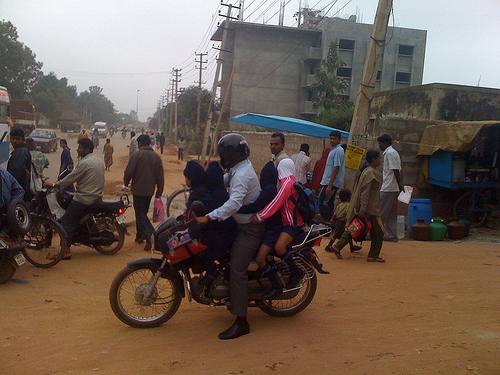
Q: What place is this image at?
A: It is at the town.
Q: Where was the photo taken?
A: It was taken at the town.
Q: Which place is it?
A: It is a town.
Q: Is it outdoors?
A: Yes, it is outdoors.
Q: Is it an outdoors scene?
A: Yes, it is outdoors.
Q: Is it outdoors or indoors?
A: It is outdoors.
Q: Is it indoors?
A: No, it is outdoors.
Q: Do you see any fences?
A: No, there are no fences.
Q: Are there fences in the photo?
A: No, there are no fences.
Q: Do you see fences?
A: No, there are no fences.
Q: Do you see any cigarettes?
A: No, there are no cigarettes.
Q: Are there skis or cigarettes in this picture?
A: No, there are no cigarettes or skis.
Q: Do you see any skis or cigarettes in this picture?
A: No, there are no cigarettes or skis.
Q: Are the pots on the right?
A: Yes, the pots are on the right of the image.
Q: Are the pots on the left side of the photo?
A: No, the pots are on the right of the image.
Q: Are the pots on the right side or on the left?
A: The pots are on the right of the image.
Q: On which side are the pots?
A: The pots are on the right of the image.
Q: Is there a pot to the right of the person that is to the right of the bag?
A: Yes, there are pots to the right of the person.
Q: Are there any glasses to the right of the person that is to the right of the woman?
A: No, there are pots to the right of the person.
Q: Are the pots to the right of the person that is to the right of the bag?
A: Yes, the pots are to the right of the person.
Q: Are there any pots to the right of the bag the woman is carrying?
A: Yes, there are pots to the right of the bag.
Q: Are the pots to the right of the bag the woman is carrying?
A: Yes, the pots are to the right of the bag.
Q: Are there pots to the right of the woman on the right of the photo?
A: Yes, there are pots to the right of the woman.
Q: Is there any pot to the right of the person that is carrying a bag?
A: Yes, there are pots to the right of the woman.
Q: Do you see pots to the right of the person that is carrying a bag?
A: Yes, there are pots to the right of the woman.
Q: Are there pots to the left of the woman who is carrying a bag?
A: No, the pots are to the right of the woman.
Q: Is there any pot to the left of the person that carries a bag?
A: No, the pots are to the right of the woman.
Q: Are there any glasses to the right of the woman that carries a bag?
A: No, there are pots to the right of the woman.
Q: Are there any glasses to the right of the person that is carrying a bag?
A: No, there are pots to the right of the woman.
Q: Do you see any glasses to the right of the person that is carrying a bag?
A: No, there are pots to the right of the woman.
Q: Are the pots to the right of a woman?
A: Yes, the pots are to the right of a woman.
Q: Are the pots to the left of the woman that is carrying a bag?
A: No, the pots are to the right of the woman.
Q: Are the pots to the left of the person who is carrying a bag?
A: No, the pots are to the right of the woman.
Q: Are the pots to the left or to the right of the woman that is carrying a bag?
A: The pots are to the right of the woman.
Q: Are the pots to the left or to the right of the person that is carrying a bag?
A: The pots are to the right of the woman.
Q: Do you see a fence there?
A: No, there are no fences.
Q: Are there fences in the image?
A: No, there are no fences.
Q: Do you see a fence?
A: No, there are no fences.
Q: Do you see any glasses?
A: No, there are no glasses.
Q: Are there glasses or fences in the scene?
A: No, there are no glasses or fences.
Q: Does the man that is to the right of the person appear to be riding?
A: Yes, the man is riding.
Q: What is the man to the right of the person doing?
A: The man is riding.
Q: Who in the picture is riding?
A: The man is riding.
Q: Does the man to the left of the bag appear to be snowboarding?
A: No, the man is riding.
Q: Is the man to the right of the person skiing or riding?
A: The man is riding.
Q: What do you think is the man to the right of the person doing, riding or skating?
A: The man is riding.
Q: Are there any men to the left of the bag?
A: Yes, there is a man to the left of the bag.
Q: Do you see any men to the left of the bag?
A: Yes, there is a man to the left of the bag.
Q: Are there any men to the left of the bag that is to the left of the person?
A: Yes, there is a man to the left of the bag.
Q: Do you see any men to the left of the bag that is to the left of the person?
A: Yes, there is a man to the left of the bag.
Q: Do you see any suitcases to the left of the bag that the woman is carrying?
A: No, there is a man to the left of the bag.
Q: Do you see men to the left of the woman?
A: Yes, there is a man to the left of the woman.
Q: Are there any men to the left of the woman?
A: Yes, there is a man to the left of the woman.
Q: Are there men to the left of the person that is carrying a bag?
A: Yes, there is a man to the left of the woman.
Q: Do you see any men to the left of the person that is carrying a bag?
A: Yes, there is a man to the left of the woman.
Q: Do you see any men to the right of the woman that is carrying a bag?
A: No, the man is to the left of the woman.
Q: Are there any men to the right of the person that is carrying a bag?
A: No, the man is to the left of the woman.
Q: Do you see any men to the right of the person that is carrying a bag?
A: No, the man is to the left of the woman.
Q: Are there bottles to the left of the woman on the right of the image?
A: No, there is a man to the left of the woman.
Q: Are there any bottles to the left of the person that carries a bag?
A: No, there is a man to the left of the woman.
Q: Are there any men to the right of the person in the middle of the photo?
A: Yes, there is a man to the right of the person.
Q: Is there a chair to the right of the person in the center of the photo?
A: No, there is a man to the right of the person.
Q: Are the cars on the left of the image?
A: Yes, the cars are on the left of the image.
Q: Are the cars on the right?
A: No, the cars are on the left of the image.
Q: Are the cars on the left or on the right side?
A: The cars are on the left of the image.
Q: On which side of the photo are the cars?
A: The cars are on the left of the image.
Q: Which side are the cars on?
A: The cars are on the left of the image.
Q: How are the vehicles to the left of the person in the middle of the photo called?
A: The vehicles are cars.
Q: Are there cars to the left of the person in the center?
A: Yes, there are cars to the left of the person.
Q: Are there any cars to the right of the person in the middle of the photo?
A: No, the cars are to the left of the person.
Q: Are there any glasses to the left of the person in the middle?
A: No, there are cars to the left of the person.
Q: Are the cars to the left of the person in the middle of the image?
A: Yes, the cars are to the left of the person.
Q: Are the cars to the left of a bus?
A: No, the cars are to the left of the person.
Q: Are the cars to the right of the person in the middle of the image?
A: No, the cars are to the left of the person.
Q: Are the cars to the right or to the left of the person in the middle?
A: The cars are to the left of the person.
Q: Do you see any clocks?
A: No, there are no clocks.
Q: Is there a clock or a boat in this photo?
A: No, there are no clocks or boats.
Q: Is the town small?
A: Yes, the town is small.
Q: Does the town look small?
A: Yes, the town is small.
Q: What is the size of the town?
A: The town is small.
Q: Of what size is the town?
A: The town is small.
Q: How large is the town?
A: The town is small.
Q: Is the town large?
A: No, the town is small.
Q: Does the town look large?
A: No, the town is small.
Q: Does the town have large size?
A: No, the town is small.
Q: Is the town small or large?
A: The town is small.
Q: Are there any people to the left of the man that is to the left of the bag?
A: Yes, there is a person to the left of the man.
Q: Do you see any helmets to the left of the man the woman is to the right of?
A: No, there is a person to the left of the man.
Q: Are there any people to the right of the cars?
A: Yes, there is a person to the right of the cars.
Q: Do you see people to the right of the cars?
A: Yes, there is a person to the right of the cars.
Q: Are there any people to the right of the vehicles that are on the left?
A: Yes, there is a person to the right of the cars.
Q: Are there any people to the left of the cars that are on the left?
A: No, the person is to the right of the cars.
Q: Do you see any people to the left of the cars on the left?
A: No, the person is to the right of the cars.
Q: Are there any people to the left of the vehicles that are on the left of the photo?
A: No, the person is to the right of the cars.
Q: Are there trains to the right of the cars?
A: No, there is a person to the right of the cars.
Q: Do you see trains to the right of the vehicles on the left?
A: No, there is a person to the right of the cars.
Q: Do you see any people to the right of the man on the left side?
A: Yes, there is a person to the right of the man.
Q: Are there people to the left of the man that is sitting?
A: No, the person is to the right of the man.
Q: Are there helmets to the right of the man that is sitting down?
A: No, there is a person to the right of the man.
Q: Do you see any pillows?
A: No, there are no pillows.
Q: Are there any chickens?
A: No, there are no chickens.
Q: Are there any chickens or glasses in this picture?
A: No, there are no chickens or glasses.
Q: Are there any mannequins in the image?
A: No, there are no mannequins.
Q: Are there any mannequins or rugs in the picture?
A: No, there are no mannequins or rugs.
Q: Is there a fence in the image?
A: No, there are no fences.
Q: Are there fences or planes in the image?
A: No, there are no fences or planes.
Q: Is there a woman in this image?
A: Yes, there is a woman.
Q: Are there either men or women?
A: Yes, there is a woman.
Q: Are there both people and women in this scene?
A: Yes, there are both a woman and people.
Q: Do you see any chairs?
A: No, there are no chairs.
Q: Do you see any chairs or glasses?
A: No, there are no chairs or glasses.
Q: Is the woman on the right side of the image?
A: Yes, the woman is on the right of the image.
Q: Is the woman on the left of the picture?
A: No, the woman is on the right of the image.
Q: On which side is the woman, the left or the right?
A: The woman is on the right of the image.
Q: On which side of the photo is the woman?
A: The woman is on the right of the image.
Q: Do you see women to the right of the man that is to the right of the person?
A: Yes, there is a woman to the right of the man.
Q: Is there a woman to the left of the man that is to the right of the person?
A: No, the woman is to the right of the man.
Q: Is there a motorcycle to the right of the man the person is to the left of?
A: No, there is a woman to the right of the man.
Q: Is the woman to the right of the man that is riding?
A: Yes, the woman is to the right of the man.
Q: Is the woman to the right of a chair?
A: No, the woman is to the right of the man.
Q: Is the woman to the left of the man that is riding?
A: No, the woman is to the right of the man.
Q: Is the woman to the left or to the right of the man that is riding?
A: The woman is to the right of the man.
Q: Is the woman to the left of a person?
A: Yes, the woman is to the left of a person.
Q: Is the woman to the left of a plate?
A: No, the woman is to the left of a person.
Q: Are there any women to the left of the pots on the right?
A: Yes, there is a woman to the left of the pots.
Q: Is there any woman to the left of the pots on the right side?
A: Yes, there is a woman to the left of the pots.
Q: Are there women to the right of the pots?
A: No, the woman is to the left of the pots.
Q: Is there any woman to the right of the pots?
A: No, the woman is to the left of the pots.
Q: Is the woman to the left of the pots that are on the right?
A: Yes, the woman is to the left of the pots.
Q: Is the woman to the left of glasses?
A: No, the woman is to the left of the pots.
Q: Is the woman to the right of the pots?
A: No, the woman is to the left of the pots.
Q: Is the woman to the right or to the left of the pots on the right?
A: The woman is to the left of the pots.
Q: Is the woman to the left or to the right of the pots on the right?
A: The woman is to the left of the pots.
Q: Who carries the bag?
A: The woman carries the bag.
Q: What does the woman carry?
A: The woman carries a bag.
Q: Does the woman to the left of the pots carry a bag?
A: Yes, the woman carries a bag.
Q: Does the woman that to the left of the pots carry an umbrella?
A: No, the woman carries a bag.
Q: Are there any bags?
A: Yes, there is a bag.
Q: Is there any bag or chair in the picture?
A: Yes, there is a bag.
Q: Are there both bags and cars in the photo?
A: Yes, there are both a bag and a car.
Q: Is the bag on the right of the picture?
A: Yes, the bag is on the right of the image.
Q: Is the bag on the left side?
A: No, the bag is on the right of the image.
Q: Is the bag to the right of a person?
A: No, the bag is to the left of a person.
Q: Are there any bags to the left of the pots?
A: Yes, there is a bag to the left of the pots.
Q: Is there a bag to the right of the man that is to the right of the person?
A: Yes, there is a bag to the right of the man.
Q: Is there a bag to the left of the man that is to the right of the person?
A: No, the bag is to the right of the man.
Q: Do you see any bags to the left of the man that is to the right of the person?
A: No, the bag is to the right of the man.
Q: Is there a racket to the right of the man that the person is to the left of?
A: No, there is a bag to the right of the man.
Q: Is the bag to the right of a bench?
A: No, the bag is to the right of a man.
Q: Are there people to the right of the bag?
A: Yes, there is a person to the right of the bag.